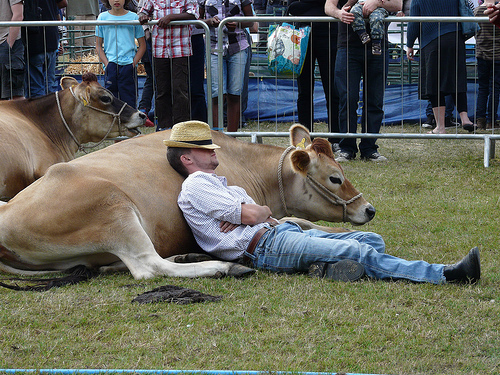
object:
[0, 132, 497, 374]
grass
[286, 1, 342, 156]
person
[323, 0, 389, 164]
man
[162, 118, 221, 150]
fedora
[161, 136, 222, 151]
band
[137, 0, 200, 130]
person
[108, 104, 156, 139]
mouth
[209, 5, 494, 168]
fence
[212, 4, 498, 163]
gate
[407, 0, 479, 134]
lady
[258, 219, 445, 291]
jeans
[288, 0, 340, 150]
man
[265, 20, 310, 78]
bag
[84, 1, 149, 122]
boy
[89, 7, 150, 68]
shirt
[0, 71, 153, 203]
brown cow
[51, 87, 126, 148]
halter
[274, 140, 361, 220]
halter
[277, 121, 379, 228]
head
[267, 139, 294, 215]
rope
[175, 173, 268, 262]
shirt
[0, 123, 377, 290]
cow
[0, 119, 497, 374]
ground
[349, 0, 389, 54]
boy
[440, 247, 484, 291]
boots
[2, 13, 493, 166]
barriers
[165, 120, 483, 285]
man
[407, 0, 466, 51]
shirt